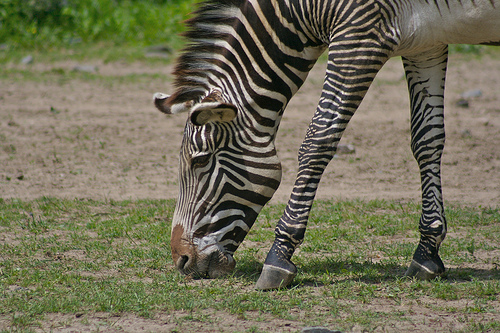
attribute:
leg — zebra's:
[252, 24, 401, 295]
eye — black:
[187, 151, 213, 166]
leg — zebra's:
[239, 20, 389, 291]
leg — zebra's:
[391, 37, 467, 285]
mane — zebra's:
[169, 0, 221, 95]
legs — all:
[253, 38, 450, 292]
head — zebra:
[154, 86, 283, 282]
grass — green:
[350, 239, 391, 300]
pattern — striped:
[247, 11, 291, 95]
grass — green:
[1, 1, 494, 84]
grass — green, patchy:
[0, 198, 497, 330]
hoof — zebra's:
[251, 261, 291, 291]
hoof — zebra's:
[401, 260, 442, 282]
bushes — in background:
[2, 2, 187, 58]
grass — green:
[24, 214, 162, 317]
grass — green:
[0, 194, 491, 316]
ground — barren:
[6, 53, 178, 210]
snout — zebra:
[168, 235, 205, 283]